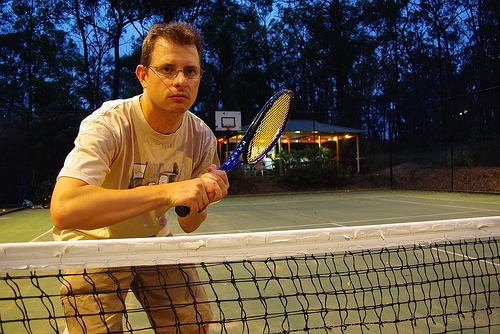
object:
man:
[47, 19, 232, 334]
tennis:
[0, 15, 497, 332]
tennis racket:
[174, 88, 296, 218]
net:
[0, 215, 500, 333]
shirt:
[51, 93, 221, 242]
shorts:
[57, 233, 216, 333]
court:
[0, 190, 498, 333]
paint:
[31, 229, 53, 242]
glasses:
[146, 64, 204, 79]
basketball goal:
[212, 108, 244, 181]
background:
[0, 0, 500, 205]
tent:
[216, 118, 368, 182]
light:
[344, 133, 355, 138]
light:
[332, 135, 338, 142]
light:
[280, 138, 288, 144]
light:
[237, 134, 243, 139]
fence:
[0, 84, 500, 217]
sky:
[0, 0, 500, 88]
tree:
[40, 0, 144, 101]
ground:
[371, 159, 500, 192]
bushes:
[273, 147, 358, 190]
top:
[0, 214, 500, 272]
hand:
[199, 166, 233, 203]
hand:
[167, 177, 210, 218]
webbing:
[246, 92, 292, 163]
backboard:
[212, 109, 243, 133]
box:
[220, 115, 237, 128]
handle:
[174, 204, 192, 217]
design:
[125, 159, 184, 194]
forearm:
[44, 182, 166, 231]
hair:
[139, 20, 204, 72]